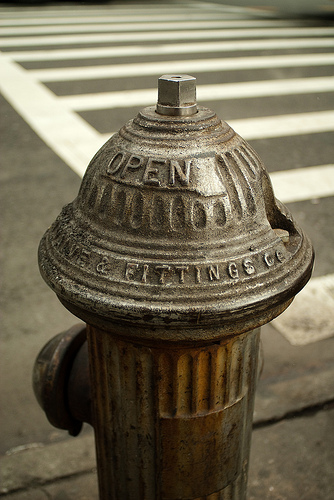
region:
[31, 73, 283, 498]
silver colored fire hydrant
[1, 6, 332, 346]
white stripes on the road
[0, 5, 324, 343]
crosswalk across the road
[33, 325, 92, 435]
place to put the hose on the hydrant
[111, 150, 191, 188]
The word "open" on the top of the hydrant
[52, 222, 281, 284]
The name of the company that made the hydrant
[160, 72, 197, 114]
giant bolt on the top of the hydrant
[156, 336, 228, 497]
area of brown rust on the bottom part of hydrant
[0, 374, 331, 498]
concrete sidewalk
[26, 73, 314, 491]
fire hydrant near the crosswalk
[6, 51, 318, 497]
The fire hydrant is near the street.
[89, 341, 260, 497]
The fire hydrant has ridges on it.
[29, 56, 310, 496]
The fire hydrant is grey.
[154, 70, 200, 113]
The nut on top of the fire hydrant.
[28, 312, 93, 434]
The nozzle on the fire hydrant.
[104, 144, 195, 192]
The word open is on the hydrant.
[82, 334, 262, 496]
The main part of the fire hydrant is shaped like a cylinder.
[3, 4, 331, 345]
The street has white lines painted on it.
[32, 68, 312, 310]
The top part of the fire hydrant.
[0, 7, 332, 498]
The street is behind the hydrant.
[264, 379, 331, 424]
low curb of the street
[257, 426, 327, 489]
paved street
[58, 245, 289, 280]
imprinted name of company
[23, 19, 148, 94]
lines of a pedestrian crossing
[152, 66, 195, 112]
nut at the top of the hydrant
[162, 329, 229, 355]
rust on the hydrant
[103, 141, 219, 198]
instructions on how to operate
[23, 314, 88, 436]
closed side valve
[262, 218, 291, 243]
small bolt on the side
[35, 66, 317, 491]
a fire hyrant in the sidewalk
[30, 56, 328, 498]
an old fire hydrant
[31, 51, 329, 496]
a rusted fire hydrant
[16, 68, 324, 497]
a grey fire hydrant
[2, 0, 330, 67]
a crosswalk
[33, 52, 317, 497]
a fire hydrant on the sidewalk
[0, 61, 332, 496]
a fire hydrant next to the curb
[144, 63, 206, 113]
a pentagon-shaped bolt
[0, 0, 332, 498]
a dry fire hydrant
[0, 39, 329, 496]
a fire hydrant near a crosswalk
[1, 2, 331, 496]
a fire hydrant in a city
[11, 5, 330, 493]
fire hydrant by curb near wide crosswalk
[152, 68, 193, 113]
angled bolt and screw on top of hydrant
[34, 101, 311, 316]
domes top of hydrant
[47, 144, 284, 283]
raised metal lettering on curved surface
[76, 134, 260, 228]
oval indentations of varying lengths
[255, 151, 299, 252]
deep arched opening with bolt at bottom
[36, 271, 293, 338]
worn black rims on metal surface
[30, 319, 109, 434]
rimmed plug protruding from side of hydrant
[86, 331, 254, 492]
thick cylindrical base with ridges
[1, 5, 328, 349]
thick white lines over gray paved street